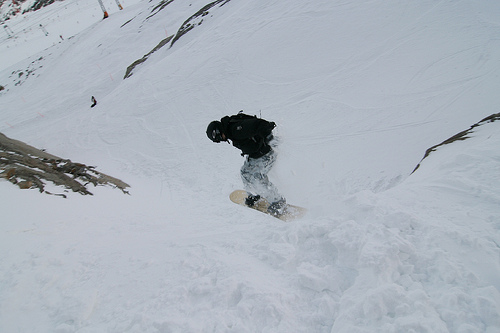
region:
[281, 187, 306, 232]
part of a board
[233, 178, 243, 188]
part of a board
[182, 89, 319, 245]
A person snow boarding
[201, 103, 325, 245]
A person on a snowboard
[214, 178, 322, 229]
A snowboard in the snow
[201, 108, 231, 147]
A person wearing a black helmet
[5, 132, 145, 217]
Rocks sticking out of the snow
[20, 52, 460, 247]
A ski slope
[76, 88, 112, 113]
A snowboarder in the distance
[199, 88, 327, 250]
A person in snow gear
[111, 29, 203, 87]
Rocks in the distance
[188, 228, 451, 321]
Snow on the ground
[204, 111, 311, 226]
a man in black on a snow board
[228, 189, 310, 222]
a white snowboard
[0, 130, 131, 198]
a stretch of stone face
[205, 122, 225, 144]
a man's black helmet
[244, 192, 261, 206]
a boot in a snowboard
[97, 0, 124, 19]
small posts in the distance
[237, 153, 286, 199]
a man's snow covered pants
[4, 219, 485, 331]
snow on a cliff side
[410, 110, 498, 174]
rock emerging from snow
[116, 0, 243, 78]
rock covered by snow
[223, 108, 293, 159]
the jacket is black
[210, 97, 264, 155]
the jacket is black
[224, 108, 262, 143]
the jacket is black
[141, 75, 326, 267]
the man is snow boarding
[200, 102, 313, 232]
person on a snowboard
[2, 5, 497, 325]
ground is covered in snow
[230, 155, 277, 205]
snow on the pants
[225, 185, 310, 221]
snowboard laying on the snow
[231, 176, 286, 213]
both feet on the snowboard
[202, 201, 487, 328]
snow is not smooth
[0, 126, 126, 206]
earth sticking out from under the snow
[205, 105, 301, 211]
person leaning forward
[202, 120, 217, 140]
black helmet on the head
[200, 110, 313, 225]
person snowboarding